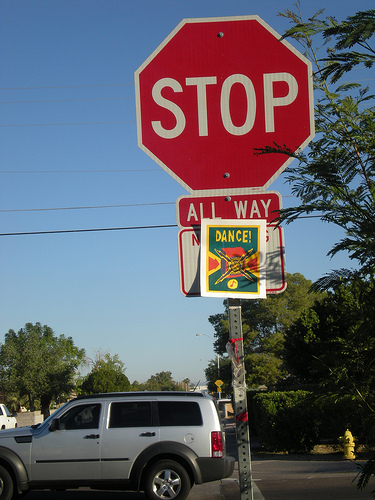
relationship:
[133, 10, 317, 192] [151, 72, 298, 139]
sign says letter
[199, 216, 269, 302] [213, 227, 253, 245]
flyer says dance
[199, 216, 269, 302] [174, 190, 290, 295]
flyer attached to signs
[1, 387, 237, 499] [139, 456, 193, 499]
car has tire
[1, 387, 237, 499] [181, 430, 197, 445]
car has gas tank door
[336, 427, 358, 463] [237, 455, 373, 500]
fire hydrant near street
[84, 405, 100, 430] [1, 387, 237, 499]
driver in car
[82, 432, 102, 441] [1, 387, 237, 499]
door handle on car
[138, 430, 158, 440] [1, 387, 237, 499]
door handle on car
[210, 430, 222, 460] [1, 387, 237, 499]
taillight on car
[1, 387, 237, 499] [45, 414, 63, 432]
car has side mirror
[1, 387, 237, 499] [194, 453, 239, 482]
suv has bumper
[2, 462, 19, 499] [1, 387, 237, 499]
partial tire on vehicle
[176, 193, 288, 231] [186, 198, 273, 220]
sign says all way